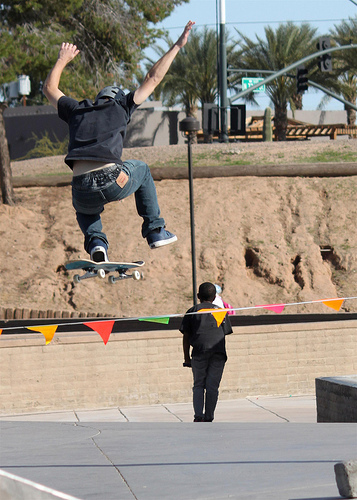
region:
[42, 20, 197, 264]
A boy doing a trick on a skateboard.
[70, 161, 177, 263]
Blue jeans the boy is wearing.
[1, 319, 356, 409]
A brick wall.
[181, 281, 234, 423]
A boy standing and facing the opposite way.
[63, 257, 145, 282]
The skateboard in the air.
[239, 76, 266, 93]
A traffic sign in the distance.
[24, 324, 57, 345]
small triangle plastic flag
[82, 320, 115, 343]
small triangle plastic flag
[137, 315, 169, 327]
small triangle plastic flag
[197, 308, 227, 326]
small triangle plastic flag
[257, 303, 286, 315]
small triangle plastic flag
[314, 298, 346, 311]
small triangle plastic flag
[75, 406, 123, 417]
white square on concrete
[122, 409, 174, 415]
white square on concrete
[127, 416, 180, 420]
white square on concrete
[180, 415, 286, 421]
white square on concrete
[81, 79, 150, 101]
boy has grery helmet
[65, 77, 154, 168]
boy has black shirt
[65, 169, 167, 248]
boy has blue pants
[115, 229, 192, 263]
boy has grey shoes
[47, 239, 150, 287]
boy jumps on skateboard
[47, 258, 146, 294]
white wheels on skateboard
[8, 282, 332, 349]
colorful flags under boy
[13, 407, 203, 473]
concrete is dark grey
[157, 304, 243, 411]
boy is walking away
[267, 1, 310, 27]
blue and clear sky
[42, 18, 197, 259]
skater doing a kick flip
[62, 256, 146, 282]
board flying though the air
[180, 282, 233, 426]
kid in front of the skater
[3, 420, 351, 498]
concrete pad to land on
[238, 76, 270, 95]
green street sign in the distance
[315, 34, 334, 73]
black street light off in the distance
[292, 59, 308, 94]
black street light off in the distance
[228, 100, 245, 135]
black street light off in the distance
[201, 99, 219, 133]
black street light off in the distance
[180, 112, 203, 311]
light off in the distance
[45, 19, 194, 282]
Kid on skateboard up in the air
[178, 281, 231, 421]
Small standing black kid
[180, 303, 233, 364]
Small short sleeved black shirt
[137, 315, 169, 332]
Small triangular green flag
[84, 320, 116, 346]
Small triangular red flag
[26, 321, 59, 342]
Small triangular yellow flag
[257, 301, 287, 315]
Small triangular pink flag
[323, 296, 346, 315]
Small triangular orange flag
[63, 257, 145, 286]
Long wooden wheeled skateboard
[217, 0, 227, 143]
Large tall metal pole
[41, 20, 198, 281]
a skateboarder performing a trick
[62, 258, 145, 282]
a skateboard in mid air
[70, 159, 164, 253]
a pair of blue jeans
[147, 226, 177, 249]
a blue and white shoe